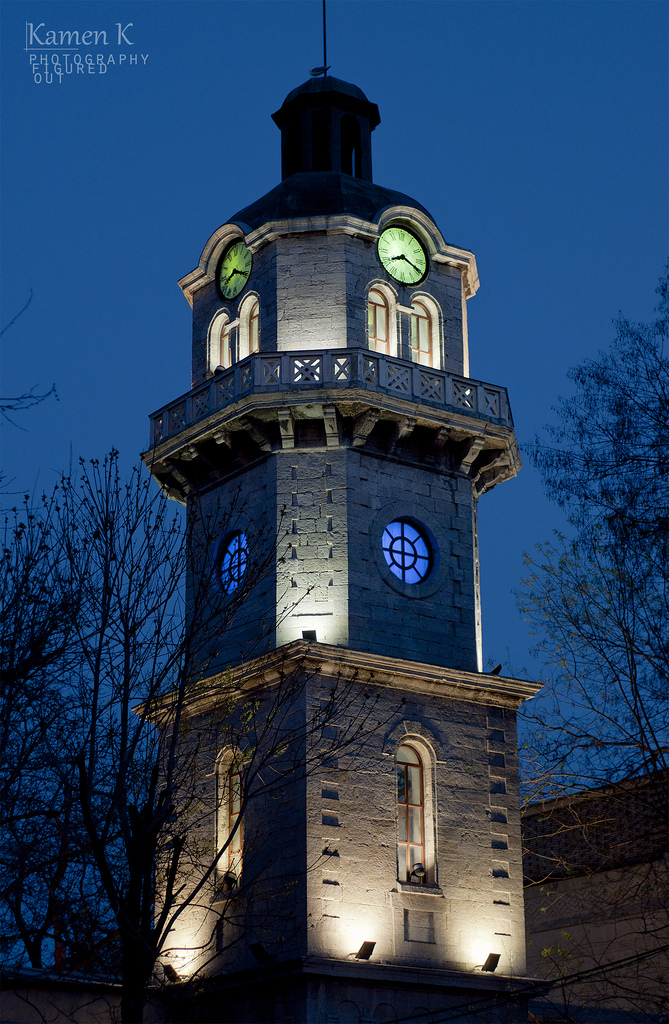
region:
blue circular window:
[199, 515, 265, 608]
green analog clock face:
[372, 221, 434, 289]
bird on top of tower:
[272, 0, 382, 177]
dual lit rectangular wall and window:
[304, 662, 530, 973]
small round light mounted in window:
[380, 715, 450, 895]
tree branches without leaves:
[1, 445, 395, 1022]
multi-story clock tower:
[125, 0, 543, 1021]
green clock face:
[209, 237, 253, 299]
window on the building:
[392, 775, 431, 877]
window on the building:
[367, 509, 430, 589]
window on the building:
[212, 524, 254, 606]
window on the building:
[237, 292, 282, 355]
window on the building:
[195, 309, 221, 368]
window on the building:
[363, 303, 390, 348]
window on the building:
[418, 319, 437, 365]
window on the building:
[209, 914, 245, 940]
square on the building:
[317, 872, 347, 892]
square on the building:
[316, 836, 334, 854]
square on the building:
[317, 816, 350, 831]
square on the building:
[305, 781, 346, 809]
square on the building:
[313, 754, 339, 775]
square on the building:
[478, 855, 504, 875]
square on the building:
[486, 829, 512, 843]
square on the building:
[484, 767, 516, 802]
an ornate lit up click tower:
[131, 1, 560, 1021]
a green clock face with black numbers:
[376, 226, 428, 284]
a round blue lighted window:
[366, 500, 452, 599]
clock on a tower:
[371, 216, 429, 282]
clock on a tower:
[211, 244, 257, 309]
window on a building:
[209, 742, 251, 870]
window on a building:
[366, 274, 392, 375]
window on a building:
[409, 286, 452, 380]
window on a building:
[205, 303, 241, 368]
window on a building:
[233, 291, 259, 352]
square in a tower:
[310, 859, 342, 886]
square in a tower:
[318, 802, 341, 826]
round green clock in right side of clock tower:
[378, 221, 430, 292]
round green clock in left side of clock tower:
[217, 236, 260, 292]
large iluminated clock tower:
[142, 59, 524, 1021]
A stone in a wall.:
[338, 762, 381, 791]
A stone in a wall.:
[297, 548, 329, 565]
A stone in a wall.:
[299, 516, 329, 537]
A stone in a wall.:
[294, 493, 311, 507]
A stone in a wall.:
[327, 487, 345, 508]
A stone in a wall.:
[316, 781, 341, 809]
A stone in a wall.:
[324, 808, 346, 829]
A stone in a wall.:
[318, 906, 358, 945]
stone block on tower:
[494, 929, 513, 950]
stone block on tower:
[485, 895, 511, 922]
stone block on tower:
[488, 874, 516, 895]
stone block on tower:
[491, 844, 508, 869]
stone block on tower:
[486, 815, 514, 844]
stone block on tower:
[486, 756, 509, 782]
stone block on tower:
[483, 733, 507, 754]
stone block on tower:
[475, 708, 509, 734]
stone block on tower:
[320, 817, 342, 838]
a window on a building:
[205, 307, 237, 371]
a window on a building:
[242, 292, 263, 354]